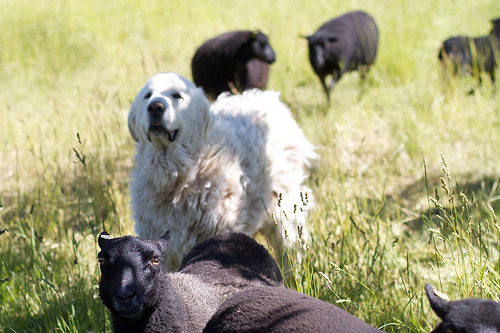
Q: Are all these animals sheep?
A: Yes, all the animals are sheep.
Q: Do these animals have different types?
A: No, all the animals are sheep.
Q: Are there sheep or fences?
A: Yes, there is a sheep.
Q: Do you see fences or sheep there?
A: Yes, there is a sheep.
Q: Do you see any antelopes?
A: No, there are no antelopes.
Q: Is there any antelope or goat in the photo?
A: No, there are no antelopes or goats.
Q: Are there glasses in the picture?
A: No, there are no glasses.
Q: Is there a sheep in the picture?
A: Yes, there is a sheep.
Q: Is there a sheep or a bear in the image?
A: Yes, there is a sheep.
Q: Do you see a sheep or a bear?
A: Yes, there is a sheep.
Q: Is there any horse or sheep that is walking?
A: Yes, the sheep is walking.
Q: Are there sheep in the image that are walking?
A: Yes, there is a sheep that is walking.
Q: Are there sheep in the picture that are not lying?
A: Yes, there is a sheep that is walking.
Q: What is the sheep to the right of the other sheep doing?
A: The sheep is walking.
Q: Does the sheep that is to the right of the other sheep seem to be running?
A: No, the sheep is walking.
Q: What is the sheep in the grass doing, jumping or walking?
A: The sheep is walking.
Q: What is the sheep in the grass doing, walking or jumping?
A: The sheep is walking.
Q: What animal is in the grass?
A: The animal is a sheep.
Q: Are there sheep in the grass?
A: Yes, there is a sheep in the grass.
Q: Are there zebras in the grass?
A: No, there is a sheep in the grass.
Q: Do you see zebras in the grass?
A: No, there is a sheep in the grass.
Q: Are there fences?
A: No, there are no fences.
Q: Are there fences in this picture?
A: No, there are no fences.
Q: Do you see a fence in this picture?
A: No, there are no fences.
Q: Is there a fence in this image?
A: No, there are no fences.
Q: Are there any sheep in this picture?
A: Yes, there is a sheep.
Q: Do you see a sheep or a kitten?
A: Yes, there is a sheep.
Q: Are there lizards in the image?
A: No, there are no lizards.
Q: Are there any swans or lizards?
A: No, there are no lizards or swans.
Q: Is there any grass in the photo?
A: Yes, there is grass.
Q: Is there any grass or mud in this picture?
A: Yes, there is grass.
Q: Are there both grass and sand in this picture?
A: No, there is grass but no sand.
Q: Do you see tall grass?
A: Yes, there is tall grass.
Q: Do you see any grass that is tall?
A: Yes, there is grass that is tall.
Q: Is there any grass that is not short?
A: Yes, there is tall grass.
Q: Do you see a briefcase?
A: No, there are no briefcases.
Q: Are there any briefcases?
A: No, there are no briefcases.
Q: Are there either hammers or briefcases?
A: No, there are no briefcases or hammers.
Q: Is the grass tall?
A: Yes, the grass is tall.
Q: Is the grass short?
A: No, the grass is tall.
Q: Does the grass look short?
A: No, the grass is tall.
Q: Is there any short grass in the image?
A: No, there is grass but it is tall.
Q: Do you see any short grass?
A: No, there is grass but it is tall.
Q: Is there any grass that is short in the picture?
A: No, there is grass but it is tall.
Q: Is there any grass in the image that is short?
A: No, there is grass but it is tall.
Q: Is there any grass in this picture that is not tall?
A: No, there is grass but it is tall.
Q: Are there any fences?
A: No, there are no fences.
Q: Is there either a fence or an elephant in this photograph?
A: No, there are no fences or elephants.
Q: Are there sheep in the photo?
A: Yes, there is a sheep.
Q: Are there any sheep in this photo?
A: Yes, there is a sheep.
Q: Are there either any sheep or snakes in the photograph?
A: Yes, there is a sheep.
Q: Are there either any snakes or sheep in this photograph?
A: Yes, there is a sheep.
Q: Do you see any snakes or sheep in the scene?
A: Yes, there is a sheep.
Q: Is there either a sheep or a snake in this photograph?
A: Yes, there is a sheep.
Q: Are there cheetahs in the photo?
A: No, there are no cheetahs.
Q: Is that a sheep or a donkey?
A: That is a sheep.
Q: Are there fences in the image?
A: No, there are no fences.